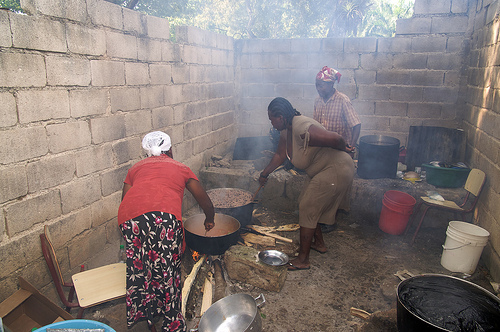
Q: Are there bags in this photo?
A: No, there are no bags.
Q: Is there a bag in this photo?
A: No, there are no bags.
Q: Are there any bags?
A: No, there are no bags.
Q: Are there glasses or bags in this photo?
A: No, there are no bags or glasses.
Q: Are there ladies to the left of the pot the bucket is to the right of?
A: Yes, there is a lady to the left of the pot.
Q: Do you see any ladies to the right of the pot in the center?
A: No, the lady is to the left of the pot.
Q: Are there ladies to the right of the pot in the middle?
A: No, the lady is to the left of the pot.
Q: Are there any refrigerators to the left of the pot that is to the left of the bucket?
A: No, there is a lady to the left of the pot.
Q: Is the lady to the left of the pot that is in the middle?
A: Yes, the lady is to the left of the pot.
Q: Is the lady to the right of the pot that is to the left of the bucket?
A: No, the lady is to the left of the pot.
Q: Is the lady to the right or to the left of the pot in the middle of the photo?
A: The lady is to the left of the pot.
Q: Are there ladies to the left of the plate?
A: Yes, there is a lady to the left of the plate.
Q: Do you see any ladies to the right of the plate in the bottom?
A: No, the lady is to the left of the plate.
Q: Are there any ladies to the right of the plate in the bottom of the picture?
A: No, the lady is to the left of the plate.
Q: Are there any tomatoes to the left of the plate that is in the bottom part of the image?
A: No, there is a lady to the left of the plate.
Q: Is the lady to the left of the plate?
A: Yes, the lady is to the left of the plate.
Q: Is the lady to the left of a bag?
A: No, the lady is to the left of the plate.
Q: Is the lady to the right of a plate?
A: No, the lady is to the left of a plate.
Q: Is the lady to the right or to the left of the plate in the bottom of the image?
A: The lady is to the left of the plate.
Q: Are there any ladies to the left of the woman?
A: Yes, there is a lady to the left of the woman.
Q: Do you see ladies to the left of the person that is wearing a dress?
A: Yes, there is a lady to the left of the woman.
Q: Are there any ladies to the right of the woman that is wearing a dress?
A: No, the lady is to the left of the woman.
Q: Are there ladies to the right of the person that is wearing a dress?
A: No, the lady is to the left of the woman.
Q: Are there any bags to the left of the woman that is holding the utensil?
A: No, there is a lady to the left of the woman.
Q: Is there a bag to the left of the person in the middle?
A: No, there is a lady to the left of the woman.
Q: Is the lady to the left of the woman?
A: Yes, the lady is to the left of the woman.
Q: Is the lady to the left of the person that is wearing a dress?
A: Yes, the lady is to the left of the woman.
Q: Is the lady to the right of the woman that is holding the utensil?
A: No, the lady is to the left of the woman.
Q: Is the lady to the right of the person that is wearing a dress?
A: No, the lady is to the left of the woman.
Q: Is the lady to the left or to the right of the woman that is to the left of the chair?
A: The lady is to the left of the woman.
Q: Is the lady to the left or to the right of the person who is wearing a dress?
A: The lady is to the left of the woman.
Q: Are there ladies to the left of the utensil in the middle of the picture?
A: Yes, there is a lady to the left of the utensil.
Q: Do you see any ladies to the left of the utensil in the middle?
A: Yes, there is a lady to the left of the utensil.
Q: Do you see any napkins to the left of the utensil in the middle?
A: No, there is a lady to the left of the utensil.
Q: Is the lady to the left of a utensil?
A: Yes, the lady is to the left of a utensil.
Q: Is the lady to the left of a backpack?
A: No, the lady is to the left of a utensil.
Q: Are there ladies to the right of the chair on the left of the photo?
A: Yes, there is a lady to the right of the chair.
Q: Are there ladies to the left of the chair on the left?
A: No, the lady is to the right of the chair.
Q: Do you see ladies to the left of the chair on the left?
A: No, the lady is to the right of the chair.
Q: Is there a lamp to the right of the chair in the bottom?
A: No, there is a lady to the right of the chair.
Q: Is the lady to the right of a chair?
A: Yes, the lady is to the right of a chair.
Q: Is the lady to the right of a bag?
A: No, the lady is to the right of a chair.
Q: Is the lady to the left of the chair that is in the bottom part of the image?
A: No, the lady is to the right of the chair.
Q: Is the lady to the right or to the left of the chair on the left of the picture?
A: The lady is to the right of the chair.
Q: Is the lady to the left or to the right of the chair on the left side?
A: The lady is to the right of the chair.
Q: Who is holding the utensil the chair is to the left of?
A: The lady is holding the utensil.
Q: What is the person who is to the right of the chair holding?
A: The lady is holding the utensil.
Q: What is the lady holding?
A: The lady is holding the utensil.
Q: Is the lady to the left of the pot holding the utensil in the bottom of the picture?
A: Yes, the lady is holding the utensil.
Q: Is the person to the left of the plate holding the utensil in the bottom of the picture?
A: Yes, the lady is holding the utensil.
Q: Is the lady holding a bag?
A: No, the lady is holding the utensil.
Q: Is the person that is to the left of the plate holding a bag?
A: No, the lady is holding the utensil.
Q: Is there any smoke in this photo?
A: Yes, there is smoke.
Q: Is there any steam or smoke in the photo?
A: Yes, there is smoke.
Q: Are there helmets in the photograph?
A: No, there are no helmets.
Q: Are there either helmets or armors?
A: No, there are no helmets or armors.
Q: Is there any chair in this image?
A: Yes, there is a chair.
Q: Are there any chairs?
A: Yes, there is a chair.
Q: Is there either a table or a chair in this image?
A: Yes, there is a chair.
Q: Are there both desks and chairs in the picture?
A: No, there is a chair but no desks.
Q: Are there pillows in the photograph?
A: No, there are no pillows.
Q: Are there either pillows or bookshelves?
A: No, there are no pillows or bookshelves.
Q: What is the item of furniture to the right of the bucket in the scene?
A: The piece of furniture is a chair.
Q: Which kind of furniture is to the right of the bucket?
A: The piece of furniture is a chair.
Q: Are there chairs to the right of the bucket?
A: Yes, there is a chair to the right of the bucket.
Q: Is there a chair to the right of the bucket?
A: Yes, there is a chair to the right of the bucket.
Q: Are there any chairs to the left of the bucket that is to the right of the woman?
A: No, the chair is to the right of the bucket.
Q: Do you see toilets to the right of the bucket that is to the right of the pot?
A: No, there is a chair to the right of the bucket.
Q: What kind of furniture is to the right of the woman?
A: The piece of furniture is a chair.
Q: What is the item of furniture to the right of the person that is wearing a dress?
A: The piece of furniture is a chair.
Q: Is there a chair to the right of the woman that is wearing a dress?
A: Yes, there is a chair to the right of the woman.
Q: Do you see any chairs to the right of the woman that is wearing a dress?
A: Yes, there is a chair to the right of the woman.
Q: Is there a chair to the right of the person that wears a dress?
A: Yes, there is a chair to the right of the woman.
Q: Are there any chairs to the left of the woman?
A: No, the chair is to the right of the woman.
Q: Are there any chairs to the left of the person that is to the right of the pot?
A: No, the chair is to the right of the woman.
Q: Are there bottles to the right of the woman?
A: No, there is a chair to the right of the woman.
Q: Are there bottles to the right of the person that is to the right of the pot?
A: No, there is a chair to the right of the woman.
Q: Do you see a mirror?
A: No, there are no mirrors.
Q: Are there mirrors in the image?
A: No, there are no mirrors.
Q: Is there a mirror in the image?
A: No, there are no mirrors.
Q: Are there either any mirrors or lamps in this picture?
A: No, there are no mirrors or lamps.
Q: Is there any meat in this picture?
A: No, there is no meat.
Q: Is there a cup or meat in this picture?
A: No, there are no meat or cups.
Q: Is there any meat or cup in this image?
A: No, there are no meat or cups.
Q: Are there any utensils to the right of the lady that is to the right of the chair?
A: Yes, there is a utensil to the right of the lady.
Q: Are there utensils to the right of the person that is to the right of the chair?
A: Yes, there is a utensil to the right of the lady.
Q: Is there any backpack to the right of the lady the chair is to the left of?
A: No, there is a utensil to the right of the lady.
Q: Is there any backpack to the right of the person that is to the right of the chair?
A: No, there is a utensil to the right of the lady.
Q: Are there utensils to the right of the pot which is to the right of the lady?
A: Yes, there is a utensil to the right of the pot.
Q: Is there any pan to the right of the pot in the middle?
A: No, there is a utensil to the right of the pot.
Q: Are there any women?
A: Yes, there is a woman.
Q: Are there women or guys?
A: Yes, there is a woman.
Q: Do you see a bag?
A: No, there are no bags.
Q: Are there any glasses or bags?
A: No, there are no bags or glasses.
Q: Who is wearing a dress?
A: The woman is wearing a dress.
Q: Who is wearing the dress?
A: The woman is wearing a dress.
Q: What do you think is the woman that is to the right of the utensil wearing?
A: The woman is wearing a dress.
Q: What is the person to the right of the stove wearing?
A: The woman is wearing a dress.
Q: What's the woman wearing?
A: The woman is wearing a dress.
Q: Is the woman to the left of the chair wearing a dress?
A: Yes, the woman is wearing a dress.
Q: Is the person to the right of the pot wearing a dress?
A: Yes, the woman is wearing a dress.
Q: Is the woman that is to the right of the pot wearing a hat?
A: No, the woman is wearing a dress.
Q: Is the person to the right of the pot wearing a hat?
A: No, the woman is wearing a dress.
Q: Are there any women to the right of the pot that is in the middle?
A: Yes, there is a woman to the right of the pot.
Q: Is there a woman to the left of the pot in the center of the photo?
A: No, the woman is to the right of the pot.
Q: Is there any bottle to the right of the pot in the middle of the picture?
A: No, there is a woman to the right of the pot.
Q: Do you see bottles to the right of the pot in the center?
A: No, there is a woman to the right of the pot.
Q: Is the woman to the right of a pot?
A: Yes, the woman is to the right of a pot.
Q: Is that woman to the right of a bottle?
A: No, the woman is to the right of a pot.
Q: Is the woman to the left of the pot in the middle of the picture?
A: No, the woman is to the right of the pot.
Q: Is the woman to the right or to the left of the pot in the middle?
A: The woman is to the right of the pot.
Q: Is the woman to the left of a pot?
A: Yes, the woman is to the left of a pot.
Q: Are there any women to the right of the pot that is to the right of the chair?
A: Yes, there is a woman to the right of the pot.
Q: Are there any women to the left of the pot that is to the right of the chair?
A: No, the woman is to the right of the pot.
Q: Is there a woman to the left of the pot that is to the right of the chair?
A: No, the woman is to the right of the pot.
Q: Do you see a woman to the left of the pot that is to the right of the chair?
A: No, the woman is to the right of the pot.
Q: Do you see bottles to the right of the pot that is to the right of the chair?
A: No, there is a woman to the right of the pot.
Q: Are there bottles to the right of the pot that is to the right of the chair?
A: No, there is a woman to the right of the pot.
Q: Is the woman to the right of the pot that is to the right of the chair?
A: Yes, the woman is to the right of the pot.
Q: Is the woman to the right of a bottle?
A: No, the woman is to the right of the pot.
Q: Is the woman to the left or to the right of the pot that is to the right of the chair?
A: The woman is to the right of the pot.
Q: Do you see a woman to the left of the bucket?
A: Yes, there is a woman to the left of the bucket.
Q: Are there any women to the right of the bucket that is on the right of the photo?
A: No, the woman is to the left of the bucket.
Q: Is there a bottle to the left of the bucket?
A: No, there is a woman to the left of the bucket.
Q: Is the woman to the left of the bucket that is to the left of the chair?
A: Yes, the woman is to the left of the bucket.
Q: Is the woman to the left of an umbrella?
A: No, the woman is to the left of the bucket.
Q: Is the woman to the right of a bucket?
A: No, the woman is to the left of a bucket.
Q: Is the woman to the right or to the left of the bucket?
A: The woman is to the left of the bucket.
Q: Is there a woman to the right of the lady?
A: Yes, there is a woman to the right of the lady.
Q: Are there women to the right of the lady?
A: Yes, there is a woman to the right of the lady.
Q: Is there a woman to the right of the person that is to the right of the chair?
A: Yes, there is a woman to the right of the lady.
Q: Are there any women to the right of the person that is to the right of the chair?
A: Yes, there is a woman to the right of the lady.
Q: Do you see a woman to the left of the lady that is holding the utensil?
A: No, the woman is to the right of the lady.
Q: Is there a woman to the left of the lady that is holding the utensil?
A: No, the woman is to the right of the lady.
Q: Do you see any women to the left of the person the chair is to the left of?
A: No, the woman is to the right of the lady.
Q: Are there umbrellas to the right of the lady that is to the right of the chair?
A: No, there is a woman to the right of the lady.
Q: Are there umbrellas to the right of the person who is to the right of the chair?
A: No, there is a woman to the right of the lady.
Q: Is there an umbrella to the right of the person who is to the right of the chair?
A: No, there is a woman to the right of the lady.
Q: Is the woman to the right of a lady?
A: Yes, the woman is to the right of a lady.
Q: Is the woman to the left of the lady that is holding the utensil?
A: No, the woman is to the right of the lady.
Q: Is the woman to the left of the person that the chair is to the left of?
A: No, the woman is to the right of the lady.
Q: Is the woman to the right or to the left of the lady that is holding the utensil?
A: The woman is to the right of the lady.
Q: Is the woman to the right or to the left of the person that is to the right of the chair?
A: The woman is to the right of the lady.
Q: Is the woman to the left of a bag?
A: No, the woman is to the left of the chair.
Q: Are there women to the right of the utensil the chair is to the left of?
A: Yes, there is a woman to the right of the utensil.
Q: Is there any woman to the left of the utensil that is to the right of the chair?
A: No, the woman is to the right of the utensil.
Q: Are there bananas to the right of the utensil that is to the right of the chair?
A: No, there is a woman to the right of the utensil.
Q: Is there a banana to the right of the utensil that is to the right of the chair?
A: No, there is a woman to the right of the utensil.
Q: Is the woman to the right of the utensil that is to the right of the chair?
A: Yes, the woman is to the right of the utensil.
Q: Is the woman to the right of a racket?
A: No, the woman is to the right of the utensil.